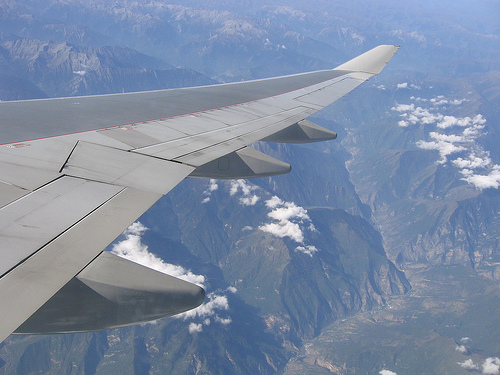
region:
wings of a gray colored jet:
[1, 42, 401, 351]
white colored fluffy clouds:
[105, 73, 499, 373]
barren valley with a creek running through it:
[280, 113, 499, 374]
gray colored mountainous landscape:
[2, 0, 499, 372]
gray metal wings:
[1, 42, 399, 349]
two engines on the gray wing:
[189, 116, 337, 181]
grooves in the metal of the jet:
[58, 138, 196, 195]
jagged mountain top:
[6, 35, 123, 84]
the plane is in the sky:
[40, 78, 411, 314]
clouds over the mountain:
[220, 185, 446, 301]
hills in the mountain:
[255, 238, 363, 350]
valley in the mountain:
[346, 230, 488, 341]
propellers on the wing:
[62, 198, 317, 374]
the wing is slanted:
[269, 45, 497, 118]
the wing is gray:
[35, 58, 370, 123]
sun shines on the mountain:
[39, 23, 102, 95]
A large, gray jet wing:
[0, 44, 397, 348]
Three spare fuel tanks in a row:
[10, 120, 337, 334]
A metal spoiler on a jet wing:
[59, 139, 194, 194]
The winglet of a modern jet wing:
[332, 43, 399, 73]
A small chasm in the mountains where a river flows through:
[340, 124, 401, 272]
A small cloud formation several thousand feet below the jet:
[389, 83, 497, 190]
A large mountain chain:
[2, 2, 498, 372]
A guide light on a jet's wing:
[7, 140, 30, 149]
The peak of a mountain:
[3, 38, 102, 65]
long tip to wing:
[0, 35, 409, 297]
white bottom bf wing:
[55, 241, 229, 333]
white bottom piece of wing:
[203, 150, 290, 190]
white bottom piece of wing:
[276, 110, 341, 147]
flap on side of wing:
[46, 131, 208, 203]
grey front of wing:
[0, 90, 127, 139]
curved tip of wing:
[306, 28, 405, 92]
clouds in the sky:
[354, 96, 491, 199]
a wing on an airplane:
[8, 22, 423, 359]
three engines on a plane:
[8, 87, 366, 344]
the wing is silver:
[64, 20, 423, 191]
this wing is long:
[9, 62, 333, 296]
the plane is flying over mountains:
[188, 195, 438, 372]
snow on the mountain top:
[219, 187, 334, 277]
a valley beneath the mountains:
[272, 275, 472, 374]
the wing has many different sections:
[18, 62, 254, 296]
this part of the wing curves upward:
[1, 55, 377, 143]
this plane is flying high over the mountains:
[7, 23, 448, 353]